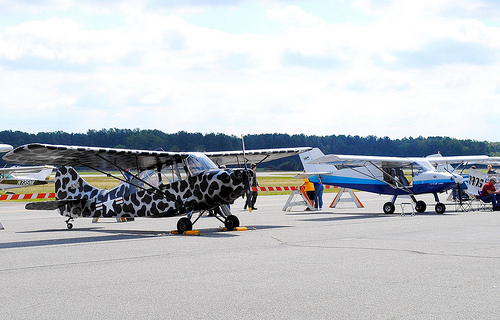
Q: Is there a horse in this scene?
A: No, there are no horses.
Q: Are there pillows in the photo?
A: No, there are no pillows.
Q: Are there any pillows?
A: No, there are no pillows.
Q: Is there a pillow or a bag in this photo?
A: No, there are no pillows or bags.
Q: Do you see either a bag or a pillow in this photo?
A: No, there are no pillows or bags.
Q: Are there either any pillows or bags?
A: No, there are no pillows or bags.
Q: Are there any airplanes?
A: Yes, there is an airplane.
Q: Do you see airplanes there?
A: Yes, there is an airplane.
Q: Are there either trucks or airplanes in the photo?
A: Yes, there is an airplane.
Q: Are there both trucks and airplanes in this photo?
A: No, there is an airplane but no trucks.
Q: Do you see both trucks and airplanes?
A: No, there is an airplane but no trucks.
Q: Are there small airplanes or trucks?
A: Yes, there is a small airplane.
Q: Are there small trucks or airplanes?
A: Yes, there is a small airplane.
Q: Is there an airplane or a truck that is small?
A: Yes, the airplane is small.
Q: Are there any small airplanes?
A: Yes, there is a small airplane.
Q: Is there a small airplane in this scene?
A: Yes, there is a small airplane.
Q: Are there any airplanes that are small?
A: Yes, there is an airplane that is small.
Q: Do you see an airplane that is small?
A: Yes, there is an airplane that is small.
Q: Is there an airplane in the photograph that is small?
A: Yes, there is an airplane that is small.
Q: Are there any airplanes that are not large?
A: Yes, there is a small airplane.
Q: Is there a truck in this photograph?
A: No, there are no trucks.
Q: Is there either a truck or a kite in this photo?
A: No, there are no trucks or kites.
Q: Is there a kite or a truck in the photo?
A: No, there are no trucks or kites.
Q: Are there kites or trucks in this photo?
A: No, there are no trucks or kites.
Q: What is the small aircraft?
A: The aircraft is an airplane.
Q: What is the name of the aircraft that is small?
A: The aircraft is an airplane.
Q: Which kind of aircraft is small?
A: The aircraft is an airplane.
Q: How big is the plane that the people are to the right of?
A: The airplane is small.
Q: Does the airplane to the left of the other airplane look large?
A: No, the plane is small.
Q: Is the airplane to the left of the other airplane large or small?
A: The plane is small.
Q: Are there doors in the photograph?
A: Yes, there is a door.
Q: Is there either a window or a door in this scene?
A: Yes, there is a door.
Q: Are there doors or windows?
A: Yes, there is a door.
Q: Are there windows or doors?
A: Yes, there is a door.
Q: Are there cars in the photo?
A: No, there are no cars.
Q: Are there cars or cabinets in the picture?
A: No, there are no cars or cabinets.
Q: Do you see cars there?
A: No, there are no cars.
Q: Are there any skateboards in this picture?
A: No, there are no skateboards.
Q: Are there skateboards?
A: No, there are no skateboards.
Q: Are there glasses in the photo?
A: No, there are no glasses.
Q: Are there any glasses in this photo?
A: No, there are no glasses.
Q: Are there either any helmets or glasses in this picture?
A: No, there are no glasses or helmets.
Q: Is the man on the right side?
A: Yes, the man is on the right of the image.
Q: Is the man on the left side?
A: No, the man is on the right of the image.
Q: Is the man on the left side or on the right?
A: The man is on the right of the image.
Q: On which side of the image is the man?
A: The man is on the right of the image.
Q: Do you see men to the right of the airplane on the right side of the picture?
A: Yes, there is a man to the right of the airplane.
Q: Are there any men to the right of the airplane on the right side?
A: Yes, there is a man to the right of the airplane.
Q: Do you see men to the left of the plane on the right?
A: No, the man is to the right of the plane.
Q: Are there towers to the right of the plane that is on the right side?
A: No, there is a man to the right of the airplane.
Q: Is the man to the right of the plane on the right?
A: Yes, the man is to the right of the plane.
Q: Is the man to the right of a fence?
A: No, the man is to the right of the plane.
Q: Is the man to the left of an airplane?
A: No, the man is to the right of an airplane.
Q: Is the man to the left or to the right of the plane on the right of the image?
A: The man is to the right of the airplane.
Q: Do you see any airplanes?
A: Yes, there is an airplane.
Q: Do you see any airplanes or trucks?
A: Yes, there is an airplane.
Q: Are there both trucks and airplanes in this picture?
A: No, there is an airplane but no trucks.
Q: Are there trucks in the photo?
A: No, there are no trucks.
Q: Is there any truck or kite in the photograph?
A: No, there are no trucks or kites.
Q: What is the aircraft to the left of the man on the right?
A: The aircraft is an airplane.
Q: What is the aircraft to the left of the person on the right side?
A: The aircraft is an airplane.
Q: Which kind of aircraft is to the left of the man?
A: The aircraft is an airplane.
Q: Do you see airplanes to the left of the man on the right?
A: Yes, there is an airplane to the left of the man.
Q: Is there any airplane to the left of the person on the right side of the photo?
A: Yes, there is an airplane to the left of the man.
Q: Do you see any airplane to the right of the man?
A: No, the airplane is to the left of the man.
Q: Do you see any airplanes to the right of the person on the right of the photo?
A: No, the airplane is to the left of the man.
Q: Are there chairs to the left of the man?
A: No, there is an airplane to the left of the man.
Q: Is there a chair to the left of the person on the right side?
A: No, there is an airplane to the left of the man.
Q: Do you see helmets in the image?
A: No, there are no helmets.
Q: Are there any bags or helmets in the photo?
A: No, there are no helmets or bags.